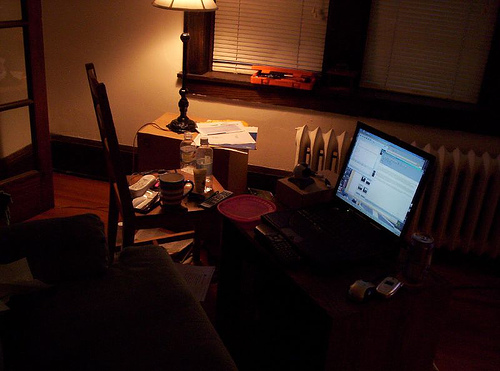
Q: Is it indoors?
A: Yes, it is indoors.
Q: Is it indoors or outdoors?
A: It is indoors.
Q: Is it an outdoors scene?
A: No, it is indoors.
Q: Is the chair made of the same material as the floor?
A: Yes, both the chair and the floor are made of wood.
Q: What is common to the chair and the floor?
A: The material, both the chair and the floor are wooden.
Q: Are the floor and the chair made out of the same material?
A: Yes, both the floor and the chair are made of wood.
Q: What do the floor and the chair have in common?
A: The material, both the floor and the chair are wooden.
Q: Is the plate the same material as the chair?
A: No, the plate is made of plastic and the chair is made of wood.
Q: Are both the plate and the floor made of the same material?
A: No, the plate is made of plastic and the floor is made of wood.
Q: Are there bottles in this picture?
A: Yes, there is a bottle.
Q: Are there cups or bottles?
A: Yes, there is a bottle.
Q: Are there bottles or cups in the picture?
A: Yes, there is a bottle.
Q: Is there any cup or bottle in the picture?
A: Yes, there is a bottle.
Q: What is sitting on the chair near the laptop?
A: The bottle is sitting on the chair.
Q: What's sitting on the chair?
A: The bottle is sitting on the chair.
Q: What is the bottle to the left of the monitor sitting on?
A: The bottle is sitting on the chair.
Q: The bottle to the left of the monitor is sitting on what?
A: The bottle is sitting on the chair.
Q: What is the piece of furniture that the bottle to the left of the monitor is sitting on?
A: The piece of furniture is a chair.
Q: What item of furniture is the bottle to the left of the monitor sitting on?
A: The bottle is sitting on the chair.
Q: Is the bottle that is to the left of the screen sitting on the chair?
A: Yes, the bottle is sitting on the chair.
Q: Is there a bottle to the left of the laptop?
A: Yes, there is a bottle to the left of the laptop.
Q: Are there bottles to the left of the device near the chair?
A: Yes, there is a bottle to the left of the laptop.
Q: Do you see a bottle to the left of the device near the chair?
A: Yes, there is a bottle to the left of the laptop.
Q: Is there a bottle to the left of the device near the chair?
A: Yes, there is a bottle to the left of the laptop.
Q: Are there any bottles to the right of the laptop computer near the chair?
A: No, the bottle is to the left of the laptop.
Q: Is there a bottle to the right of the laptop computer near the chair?
A: No, the bottle is to the left of the laptop.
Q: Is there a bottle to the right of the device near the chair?
A: No, the bottle is to the left of the laptop.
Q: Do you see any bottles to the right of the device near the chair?
A: No, the bottle is to the left of the laptop.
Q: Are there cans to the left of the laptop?
A: No, there is a bottle to the left of the laptop.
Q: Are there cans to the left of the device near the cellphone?
A: No, there is a bottle to the left of the laptop.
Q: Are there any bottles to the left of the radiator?
A: Yes, there is a bottle to the left of the radiator.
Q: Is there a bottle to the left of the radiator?
A: Yes, there is a bottle to the left of the radiator.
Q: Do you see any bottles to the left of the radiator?
A: Yes, there is a bottle to the left of the radiator.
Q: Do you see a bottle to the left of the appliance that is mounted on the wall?
A: Yes, there is a bottle to the left of the radiator.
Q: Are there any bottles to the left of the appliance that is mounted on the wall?
A: Yes, there is a bottle to the left of the radiator.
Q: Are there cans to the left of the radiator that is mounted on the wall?
A: No, there is a bottle to the left of the radiator.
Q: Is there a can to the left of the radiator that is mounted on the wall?
A: No, there is a bottle to the left of the radiator.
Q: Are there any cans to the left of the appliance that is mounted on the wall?
A: No, there is a bottle to the left of the radiator.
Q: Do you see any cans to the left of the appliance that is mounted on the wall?
A: No, there is a bottle to the left of the radiator.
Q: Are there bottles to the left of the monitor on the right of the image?
A: Yes, there is a bottle to the left of the monitor.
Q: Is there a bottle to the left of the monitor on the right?
A: Yes, there is a bottle to the left of the monitor.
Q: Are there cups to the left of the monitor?
A: No, there is a bottle to the left of the monitor.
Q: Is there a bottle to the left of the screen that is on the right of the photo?
A: Yes, there is a bottle to the left of the screen.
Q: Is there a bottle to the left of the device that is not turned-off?
A: Yes, there is a bottle to the left of the screen.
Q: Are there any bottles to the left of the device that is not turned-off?
A: Yes, there is a bottle to the left of the screen.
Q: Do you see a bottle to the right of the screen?
A: No, the bottle is to the left of the screen.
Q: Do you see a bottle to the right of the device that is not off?
A: No, the bottle is to the left of the screen.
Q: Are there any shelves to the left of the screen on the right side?
A: No, there is a bottle to the left of the screen.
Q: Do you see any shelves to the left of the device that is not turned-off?
A: No, there is a bottle to the left of the screen.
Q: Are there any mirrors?
A: No, there are no mirrors.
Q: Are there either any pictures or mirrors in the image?
A: No, there are no mirrors or pictures.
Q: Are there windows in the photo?
A: Yes, there is a window.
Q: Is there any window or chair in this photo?
A: Yes, there is a window.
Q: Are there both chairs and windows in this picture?
A: Yes, there are both a window and a chair.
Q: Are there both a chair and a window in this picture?
A: Yes, there are both a window and a chair.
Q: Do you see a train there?
A: No, there are no trains.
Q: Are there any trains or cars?
A: No, there are no trains or cars.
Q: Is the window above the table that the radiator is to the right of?
A: Yes, the window is above the table.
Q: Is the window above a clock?
A: No, the window is above the table.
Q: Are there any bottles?
A: Yes, there is a bottle.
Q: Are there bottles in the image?
A: Yes, there is a bottle.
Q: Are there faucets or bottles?
A: Yes, there is a bottle.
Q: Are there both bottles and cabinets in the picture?
A: No, there is a bottle but no cabinets.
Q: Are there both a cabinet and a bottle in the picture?
A: No, there is a bottle but no cabinets.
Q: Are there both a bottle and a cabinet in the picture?
A: No, there is a bottle but no cabinets.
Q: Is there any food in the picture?
A: No, there is no food.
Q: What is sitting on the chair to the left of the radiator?
A: The bottle is sitting on the chair.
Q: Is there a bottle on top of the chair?
A: Yes, there is a bottle on top of the chair.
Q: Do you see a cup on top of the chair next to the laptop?
A: No, there is a bottle on top of the chair.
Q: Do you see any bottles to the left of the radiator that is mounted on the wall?
A: Yes, there is a bottle to the left of the radiator.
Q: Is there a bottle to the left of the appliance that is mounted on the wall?
A: Yes, there is a bottle to the left of the radiator.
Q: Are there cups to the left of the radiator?
A: No, there is a bottle to the left of the radiator.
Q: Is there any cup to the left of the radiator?
A: No, there is a bottle to the left of the radiator.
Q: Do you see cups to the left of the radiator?
A: No, there is a bottle to the left of the radiator.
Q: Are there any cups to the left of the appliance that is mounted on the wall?
A: No, there is a bottle to the left of the radiator.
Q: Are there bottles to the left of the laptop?
A: Yes, there is a bottle to the left of the laptop.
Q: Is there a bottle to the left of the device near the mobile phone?
A: Yes, there is a bottle to the left of the laptop.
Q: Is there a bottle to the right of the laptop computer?
A: No, the bottle is to the left of the laptop computer.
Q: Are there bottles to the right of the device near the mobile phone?
A: No, the bottle is to the left of the laptop computer.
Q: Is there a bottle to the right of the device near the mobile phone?
A: No, the bottle is to the left of the laptop computer.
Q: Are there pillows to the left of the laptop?
A: No, there is a bottle to the left of the laptop.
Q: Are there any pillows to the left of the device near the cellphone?
A: No, there is a bottle to the left of the laptop.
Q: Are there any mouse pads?
A: No, there are no mouse pads.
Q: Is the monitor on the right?
A: Yes, the monitor is on the right of the image.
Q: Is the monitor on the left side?
A: No, the monitor is on the right of the image.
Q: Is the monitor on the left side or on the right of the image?
A: The monitor is on the right of the image.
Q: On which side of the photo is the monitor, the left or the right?
A: The monitor is on the right of the image.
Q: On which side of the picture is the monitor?
A: The monitor is on the right of the image.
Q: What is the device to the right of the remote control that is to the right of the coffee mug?
A: The device is a monitor.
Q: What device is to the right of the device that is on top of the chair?
A: The device is a monitor.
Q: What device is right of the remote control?
A: The device is a monitor.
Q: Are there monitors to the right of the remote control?
A: Yes, there is a monitor to the right of the remote control.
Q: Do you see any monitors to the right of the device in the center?
A: Yes, there is a monitor to the right of the remote control.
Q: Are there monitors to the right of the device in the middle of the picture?
A: Yes, there is a monitor to the right of the remote control.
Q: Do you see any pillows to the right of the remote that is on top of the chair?
A: No, there is a monitor to the right of the remote control.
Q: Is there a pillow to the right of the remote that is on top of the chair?
A: No, there is a monitor to the right of the remote control.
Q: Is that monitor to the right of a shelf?
A: No, the monitor is to the right of the remote control.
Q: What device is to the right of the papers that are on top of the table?
A: The device is a monitor.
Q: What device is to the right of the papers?
A: The device is a monitor.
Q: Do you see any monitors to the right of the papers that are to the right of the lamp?
A: Yes, there is a monitor to the right of the papers.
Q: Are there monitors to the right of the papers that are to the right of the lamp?
A: Yes, there is a monitor to the right of the papers.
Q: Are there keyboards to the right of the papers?
A: No, there is a monitor to the right of the papers.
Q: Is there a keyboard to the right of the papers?
A: No, there is a monitor to the right of the papers.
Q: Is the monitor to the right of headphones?
A: No, the monitor is to the right of the papers.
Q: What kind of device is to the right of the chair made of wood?
A: The device is a monitor.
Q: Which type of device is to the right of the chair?
A: The device is a monitor.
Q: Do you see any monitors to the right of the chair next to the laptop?
A: Yes, there is a monitor to the right of the chair.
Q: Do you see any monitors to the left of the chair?
A: No, the monitor is to the right of the chair.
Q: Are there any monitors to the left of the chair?
A: No, the monitor is to the right of the chair.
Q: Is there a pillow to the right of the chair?
A: No, there is a monitor to the right of the chair.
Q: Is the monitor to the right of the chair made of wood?
A: Yes, the monitor is to the right of the chair.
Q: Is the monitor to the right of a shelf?
A: No, the monitor is to the right of the chair.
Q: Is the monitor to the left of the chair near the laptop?
A: No, the monitor is to the right of the chair.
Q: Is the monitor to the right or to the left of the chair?
A: The monitor is to the right of the chair.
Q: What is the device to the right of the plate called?
A: The device is a monitor.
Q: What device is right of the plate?
A: The device is a monitor.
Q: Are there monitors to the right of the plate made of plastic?
A: Yes, there is a monitor to the right of the plate.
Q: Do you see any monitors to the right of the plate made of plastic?
A: Yes, there is a monitor to the right of the plate.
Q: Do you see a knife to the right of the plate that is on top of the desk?
A: No, there is a monitor to the right of the plate.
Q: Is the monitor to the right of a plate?
A: Yes, the monitor is to the right of a plate.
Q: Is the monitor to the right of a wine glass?
A: No, the monitor is to the right of a plate.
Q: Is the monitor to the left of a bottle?
A: No, the monitor is to the right of a bottle.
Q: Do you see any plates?
A: Yes, there is a plate.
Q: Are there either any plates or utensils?
A: Yes, there is a plate.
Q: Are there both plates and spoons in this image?
A: No, there is a plate but no spoons.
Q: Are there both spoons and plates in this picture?
A: No, there is a plate but no spoons.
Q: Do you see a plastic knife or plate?
A: Yes, there is a plastic plate.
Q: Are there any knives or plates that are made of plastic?
A: Yes, the plate is made of plastic.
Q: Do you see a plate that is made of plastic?
A: Yes, there is a plate that is made of plastic.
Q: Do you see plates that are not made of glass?
A: Yes, there is a plate that is made of plastic.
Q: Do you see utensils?
A: No, there are no utensils.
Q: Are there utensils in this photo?
A: No, there are no utensils.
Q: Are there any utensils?
A: No, there are no utensils.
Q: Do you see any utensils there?
A: No, there are no utensils.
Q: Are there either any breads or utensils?
A: No, there are no utensils or breads.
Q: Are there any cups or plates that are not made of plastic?
A: No, there is a plate but it is made of plastic.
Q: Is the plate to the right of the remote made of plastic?
A: Yes, the plate is made of plastic.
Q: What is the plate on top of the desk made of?
A: The plate is made of plastic.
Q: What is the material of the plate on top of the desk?
A: The plate is made of plastic.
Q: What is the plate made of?
A: The plate is made of plastic.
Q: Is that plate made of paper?
A: No, the plate is made of plastic.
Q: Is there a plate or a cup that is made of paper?
A: No, there is a plate but it is made of plastic.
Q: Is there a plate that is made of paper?
A: No, there is a plate but it is made of plastic.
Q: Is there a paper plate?
A: No, there is a plate but it is made of plastic.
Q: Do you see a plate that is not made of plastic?
A: No, there is a plate but it is made of plastic.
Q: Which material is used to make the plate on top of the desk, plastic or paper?
A: The plate is made of plastic.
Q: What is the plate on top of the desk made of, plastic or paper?
A: The plate is made of plastic.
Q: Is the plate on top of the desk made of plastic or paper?
A: The plate is made of plastic.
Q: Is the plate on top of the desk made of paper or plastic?
A: The plate is made of plastic.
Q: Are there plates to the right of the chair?
A: Yes, there is a plate to the right of the chair.